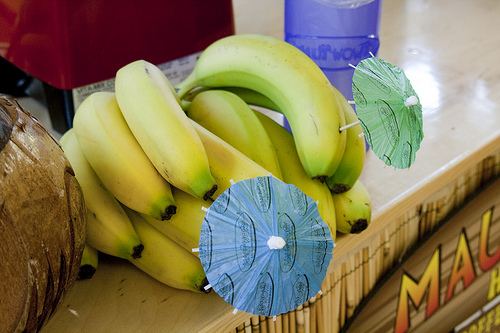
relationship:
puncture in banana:
[335, 125, 345, 136] [181, 31, 347, 179]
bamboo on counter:
[230, 150, 499, 331] [0, 0, 499, 333]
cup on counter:
[284, 1, 378, 130] [0, 0, 499, 333]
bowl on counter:
[1, 86, 87, 332] [0, 0, 499, 333]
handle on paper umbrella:
[335, 92, 422, 131] [354, 57, 422, 167]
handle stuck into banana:
[335, 92, 422, 131] [181, 31, 347, 179]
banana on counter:
[181, 31, 347, 179] [32, 0, 499, 332]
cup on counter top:
[284, 1, 378, 130] [0, 0, 499, 333]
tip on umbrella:
[267, 236, 286, 249] [190, 170, 336, 324]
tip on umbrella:
[405, 96, 419, 106] [344, 47, 427, 167]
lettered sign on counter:
[388, 206, 498, 331] [0, 0, 499, 333]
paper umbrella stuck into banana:
[354, 57, 422, 167] [174, 29, 367, 190]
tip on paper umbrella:
[394, 88, 426, 118] [354, 57, 422, 167]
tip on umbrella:
[267, 231, 288, 250] [190, 170, 336, 324]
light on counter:
[399, 64, 463, 128] [0, 0, 499, 333]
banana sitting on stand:
[58, 28, 368, 323] [29, 2, 499, 327]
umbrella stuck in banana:
[206, 206, 297, 291] [54, 19, 373, 293]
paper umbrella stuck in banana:
[354, 57, 422, 167] [186, 31, 358, 176]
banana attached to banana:
[181, 31, 347, 179] [181, 31, 347, 179]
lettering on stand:
[392, 208, 499, 332] [29, 2, 499, 327]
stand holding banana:
[29, 2, 499, 327] [64, 108, 124, 215]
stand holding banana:
[29, 2, 499, 327] [118, 64, 189, 196]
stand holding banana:
[29, 2, 499, 327] [186, 31, 343, 171]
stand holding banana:
[29, 2, 499, 327] [191, 93, 289, 177]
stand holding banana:
[29, 2, 499, 327] [278, 159, 333, 236]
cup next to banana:
[276, 1, 384, 158] [172, 27, 352, 189]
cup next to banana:
[276, 1, 384, 158] [107, 52, 225, 202]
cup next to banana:
[276, 1, 384, 158] [68, 83, 181, 220]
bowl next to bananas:
[1, 86, 87, 332] [26, 15, 391, 290]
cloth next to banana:
[1, 1, 235, 88] [72, 92, 178, 222]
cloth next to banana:
[1, 1, 235, 88] [181, 31, 347, 179]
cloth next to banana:
[1, 1, 235, 88] [188, 88, 283, 178]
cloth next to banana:
[1, 1, 235, 88] [113, 60, 218, 198]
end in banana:
[162, 206, 176, 221] [181, 31, 347, 179]